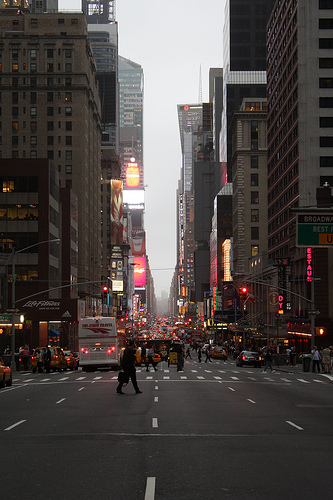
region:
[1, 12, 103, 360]
tall brown building on the corner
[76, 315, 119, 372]
a white bus with red writing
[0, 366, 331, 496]
these are lines in the street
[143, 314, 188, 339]
a lot of traffic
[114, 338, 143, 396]
a man crossing the street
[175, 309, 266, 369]
these are parked cars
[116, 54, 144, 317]
this is a glass buiding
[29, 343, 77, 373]
these are taxi cabs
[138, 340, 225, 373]
people are crossing the street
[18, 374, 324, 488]
street for vehicles to travel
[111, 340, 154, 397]
man crossing the street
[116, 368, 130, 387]
man carrying a bag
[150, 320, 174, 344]
traffic in the street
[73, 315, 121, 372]
coach bus for tourists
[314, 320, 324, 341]
traffic signal for pedestrians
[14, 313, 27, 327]
traffic signal for pedestrians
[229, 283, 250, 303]
traffic light over the street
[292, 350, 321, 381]
corner of the street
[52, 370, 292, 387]
white marks on street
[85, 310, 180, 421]
Person crossing street carrying bag.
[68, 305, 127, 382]
White and red bus in outer traffic lane.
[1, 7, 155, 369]
Large multi level floor buildings.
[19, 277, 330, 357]
Traffic lights that arch over roadway.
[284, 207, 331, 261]
Green and white street sign.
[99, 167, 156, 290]
Different types of billboards on sides of buildings.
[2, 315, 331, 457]
Four lane roadway with parking lane.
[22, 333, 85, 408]
Taxi cars sitting at corner.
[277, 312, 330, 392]
Garbage can on corner at intersection.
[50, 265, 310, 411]
Heavy traffic in downtown area.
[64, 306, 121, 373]
red and white bus parked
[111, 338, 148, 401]
guy walking across street with briefcase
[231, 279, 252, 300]
street light with red signal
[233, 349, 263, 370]
black car parked on side of street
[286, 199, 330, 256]
traffic sign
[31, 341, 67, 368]
yellow taxi van parked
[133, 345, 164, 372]
yellow taxi cab on street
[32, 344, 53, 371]
tree people walking across street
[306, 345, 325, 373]
person walking on phone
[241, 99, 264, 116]
three windows with light on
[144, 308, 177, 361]
cars on the street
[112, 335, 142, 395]
person crossing the street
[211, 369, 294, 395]
white lines on street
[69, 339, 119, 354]
tail lights on bus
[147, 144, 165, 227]
the sky is grey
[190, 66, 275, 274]
the buildings are tall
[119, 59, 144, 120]
windows on the building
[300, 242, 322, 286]
sign on the building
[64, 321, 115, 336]
back of the bus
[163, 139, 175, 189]
the weather is foggy